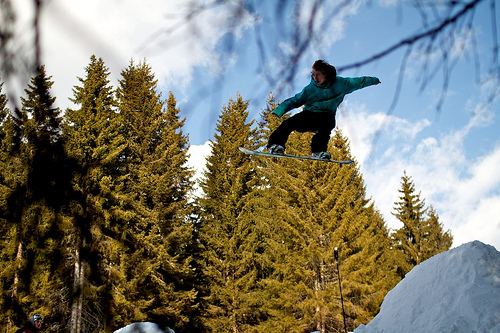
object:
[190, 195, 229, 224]
leaves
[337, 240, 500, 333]
ground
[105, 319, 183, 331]
ground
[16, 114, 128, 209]
shadow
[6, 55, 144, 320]
tree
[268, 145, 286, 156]
shoes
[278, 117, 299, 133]
knees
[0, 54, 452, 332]
forest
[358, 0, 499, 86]
branch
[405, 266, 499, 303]
snow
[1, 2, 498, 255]
clouds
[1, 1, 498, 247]
sky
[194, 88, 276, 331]
tree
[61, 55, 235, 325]
tree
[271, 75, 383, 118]
coat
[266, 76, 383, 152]
snowsuit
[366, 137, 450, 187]
clouds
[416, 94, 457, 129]
air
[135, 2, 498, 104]
tree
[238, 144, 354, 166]
board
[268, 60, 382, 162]
man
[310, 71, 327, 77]
goggles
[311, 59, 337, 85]
head